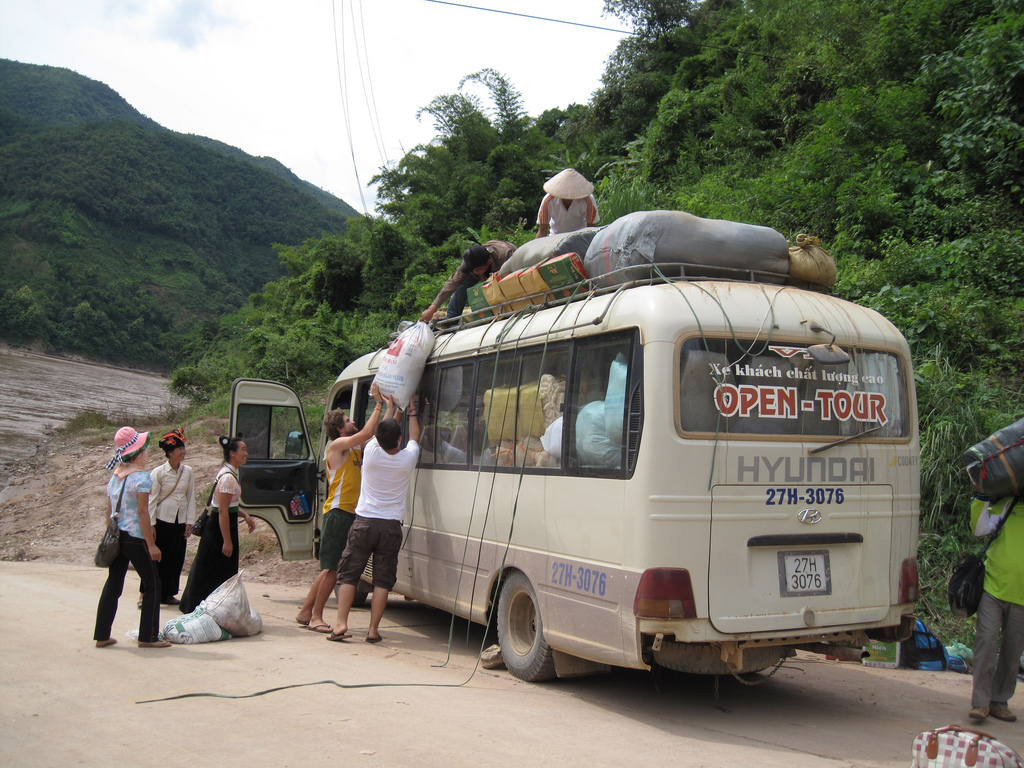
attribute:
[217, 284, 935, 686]
bus — old , white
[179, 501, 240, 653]
skirt — black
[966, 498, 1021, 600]
shirt — green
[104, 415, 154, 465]
hat — pink